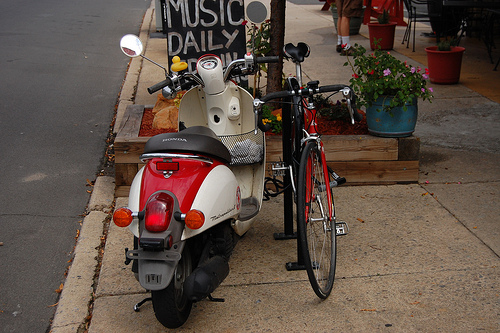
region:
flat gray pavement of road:
[5, 2, 137, 328]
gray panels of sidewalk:
[46, 1, 491, 326]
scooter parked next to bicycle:
[105, 32, 345, 287]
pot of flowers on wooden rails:
[335, 37, 430, 182]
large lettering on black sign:
[155, 0, 250, 92]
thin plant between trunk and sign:
[167, 1, 287, 101]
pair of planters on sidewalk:
[360, 1, 465, 87]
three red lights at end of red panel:
[110, 151, 220, 233]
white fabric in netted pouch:
[212, 126, 265, 167]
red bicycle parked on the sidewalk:
[269, 53, 369, 296]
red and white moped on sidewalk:
[109, 52, 271, 319]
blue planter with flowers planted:
[341, 43, 427, 134]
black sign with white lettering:
[163, 1, 250, 78]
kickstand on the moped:
[129, 293, 226, 310]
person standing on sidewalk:
[325, 1, 367, 47]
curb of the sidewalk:
[41, 0, 152, 332]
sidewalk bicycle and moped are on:
[64, 8, 494, 331]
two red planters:
[363, 11, 468, 86]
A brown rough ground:
[229, 253, 304, 331]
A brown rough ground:
[437, 130, 497, 246]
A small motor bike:
[135, 60, 354, 306]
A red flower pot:
[413, 38, 471, 83]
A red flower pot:
[362, 8, 404, 50]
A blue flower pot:
[368, 82, 430, 138]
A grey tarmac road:
[2, 183, 53, 325]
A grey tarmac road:
[4, 108, 95, 188]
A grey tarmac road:
[10, 3, 105, 120]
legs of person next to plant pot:
[325, 0, 366, 56]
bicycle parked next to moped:
[261, 33, 361, 300]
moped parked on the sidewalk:
[117, 34, 281, 321]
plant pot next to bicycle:
[337, 34, 435, 138]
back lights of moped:
[110, 192, 206, 248]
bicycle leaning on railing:
[255, 42, 357, 298]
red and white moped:
[112, 32, 283, 329]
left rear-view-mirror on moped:
[119, 34, 171, 80]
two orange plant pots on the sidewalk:
[360, 20, 462, 80]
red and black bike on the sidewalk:
[257, 42, 360, 300]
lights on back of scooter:
[98, 185, 215, 233]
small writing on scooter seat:
[146, 128, 191, 149]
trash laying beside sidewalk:
[76, 125, 117, 181]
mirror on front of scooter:
[112, 25, 167, 80]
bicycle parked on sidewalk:
[278, 41, 353, 310]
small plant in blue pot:
[341, 39, 435, 142]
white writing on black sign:
[168, 0, 243, 57]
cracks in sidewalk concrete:
[430, 170, 498, 256]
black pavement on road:
[6, 2, 101, 138]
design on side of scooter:
[224, 184, 249, 216]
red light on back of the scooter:
[140, 190, 179, 238]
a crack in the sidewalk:
[414, 178, 494, 275]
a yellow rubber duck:
[165, 51, 192, 76]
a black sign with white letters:
[155, 2, 249, 77]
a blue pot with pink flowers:
[348, 45, 430, 138]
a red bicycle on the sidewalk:
[269, 77, 349, 309]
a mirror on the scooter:
[115, 27, 170, 89]